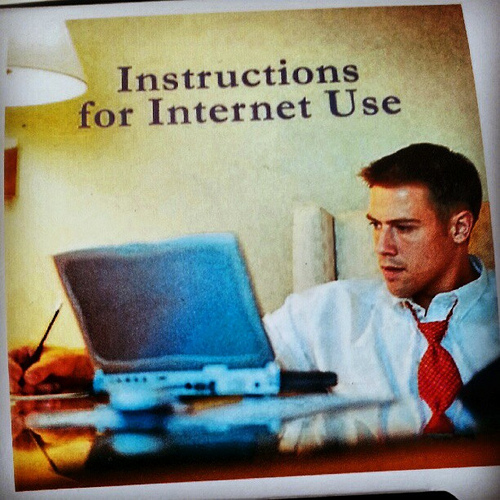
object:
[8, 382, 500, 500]
table top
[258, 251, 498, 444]
shirt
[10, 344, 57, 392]
hand holding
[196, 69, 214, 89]
lettering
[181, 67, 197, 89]
lettering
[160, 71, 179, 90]
lettering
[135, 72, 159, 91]
lettering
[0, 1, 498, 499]
advertisement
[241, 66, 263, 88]
lettering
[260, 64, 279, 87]
lettering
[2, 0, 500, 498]
book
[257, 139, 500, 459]
man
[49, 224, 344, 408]
laptop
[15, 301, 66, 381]
pencil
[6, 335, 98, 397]
hand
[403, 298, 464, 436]
tie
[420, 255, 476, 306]
neck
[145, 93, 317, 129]
internet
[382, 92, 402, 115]
lettering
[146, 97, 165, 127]
lettering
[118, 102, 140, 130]
lettering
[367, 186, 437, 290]
face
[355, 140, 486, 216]
hair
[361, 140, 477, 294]
head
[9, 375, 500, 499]
table